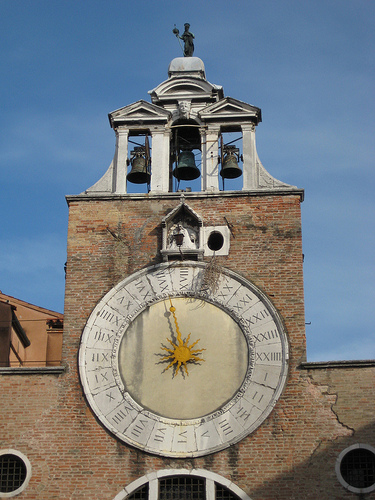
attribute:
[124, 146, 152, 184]
bell — old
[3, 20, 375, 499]
building — ancient monument, old, brick, large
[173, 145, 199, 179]
bell — green, old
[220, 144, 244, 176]
bell — old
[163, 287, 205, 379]
hand — yellow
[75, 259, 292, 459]
clock — sundial, oversized, white, large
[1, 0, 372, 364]
sky — blue, sunny, bright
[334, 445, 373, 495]
window — circular, round, small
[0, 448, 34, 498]
window — circular, round, small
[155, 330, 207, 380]
sun — yellow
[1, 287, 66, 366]
building — tan